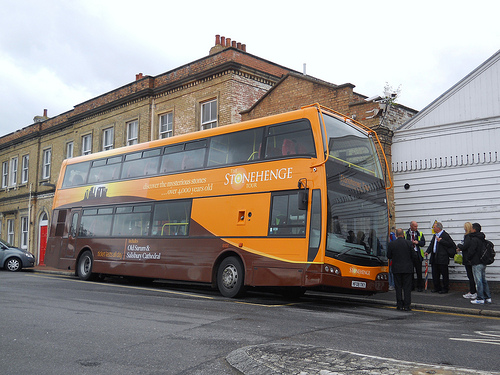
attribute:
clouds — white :
[0, 45, 114, 119]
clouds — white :
[90, 0, 499, 114]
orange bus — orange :
[43, 101, 393, 299]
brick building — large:
[3, 26, 298, 263]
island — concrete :
[226, 341, 496, 373]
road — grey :
[1, 284, 385, 373]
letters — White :
[226, 162, 297, 187]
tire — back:
[74, 248, 92, 280]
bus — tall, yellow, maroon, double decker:
[40, 101, 392, 298]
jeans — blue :
[457, 254, 493, 299]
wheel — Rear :
[217, 258, 249, 298]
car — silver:
[0, 239, 38, 271]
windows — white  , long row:
[9, 86, 228, 192]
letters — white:
[129, 168, 294, 200]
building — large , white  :
[386, 46, 493, 281]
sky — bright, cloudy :
[48, 19, 435, 35]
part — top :
[61, 107, 323, 182]